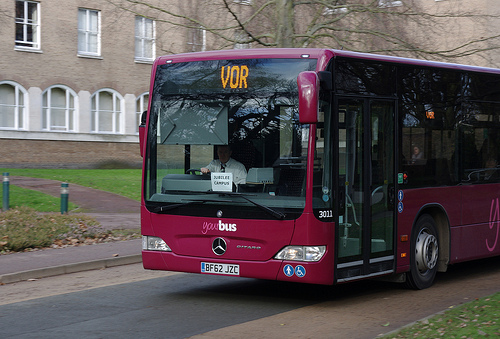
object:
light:
[273, 245, 326, 261]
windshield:
[143, 58, 318, 221]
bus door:
[334, 99, 366, 264]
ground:
[0, 169, 499, 339]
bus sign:
[220, 66, 248, 88]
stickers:
[295, 265, 306, 278]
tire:
[409, 214, 439, 289]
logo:
[211, 237, 226, 255]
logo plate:
[175, 234, 266, 258]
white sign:
[211, 172, 232, 192]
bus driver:
[200, 144, 248, 193]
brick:
[57, 58, 116, 86]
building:
[0, 0, 499, 167]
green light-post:
[60, 183, 69, 213]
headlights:
[142, 235, 171, 251]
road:
[0, 260, 498, 338]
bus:
[140, 48, 500, 292]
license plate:
[201, 262, 240, 274]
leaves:
[49, 232, 107, 248]